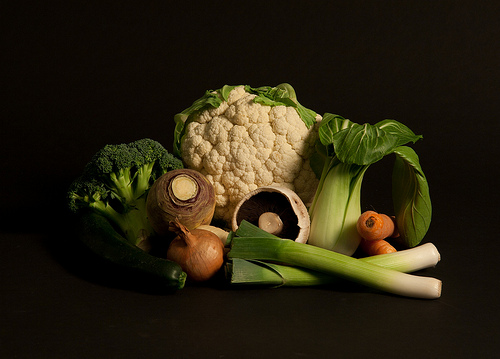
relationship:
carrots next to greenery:
[354, 209, 401, 261] [71, 74, 446, 302]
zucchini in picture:
[83, 207, 190, 293] [48, 43, 468, 328]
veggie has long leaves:
[309, 111, 436, 258] [313, 111, 434, 248]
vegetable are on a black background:
[166, 215, 233, 279] [3, 2, 498, 356]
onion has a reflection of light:
[164, 219, 224, 279] [206, 244, 220, 259]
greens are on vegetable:
[305, 112, 433, 256] [252, 81, 457, 264]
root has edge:
[188, 186, 321, 285] [227, 271, 331, 288]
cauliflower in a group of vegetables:
[171, 82, 328, 220] [58, 77, 445, 301]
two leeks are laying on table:
[237, 189, 391, 292] [3, 159, 499, 354]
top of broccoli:
[75, 136, 190, 182] [62, 135, 184, 246]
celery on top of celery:
[228, 218, 441, 300] [226, 242, 439, 282]